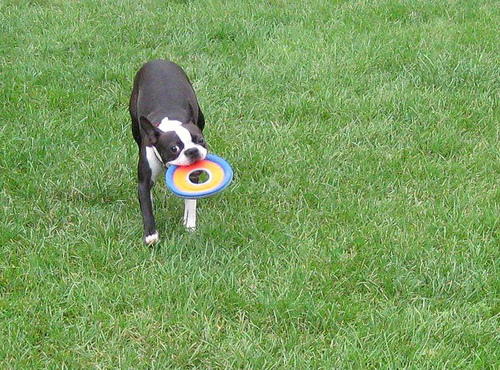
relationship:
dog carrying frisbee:
[129, 62, 204, 246] [163, 150, 235, 204]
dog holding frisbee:
[105, 102, 219, 316] [171, 156, 240, 208]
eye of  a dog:
[162, 141, 181, 160] [134, 99, 199, 232]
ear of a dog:
[142, 128, 155, 141] [128, 101, 211, 306]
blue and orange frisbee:
[216, 177, 226, 199] [167, 154, 233, 221]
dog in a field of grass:
[129, 62, 204, 246] [15, 99, 475, 348]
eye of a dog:
[195, 138, 209, 148] [136, 104, 221, 328]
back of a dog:
[149, 62, 188, 128] [124, 106, 231, 275]